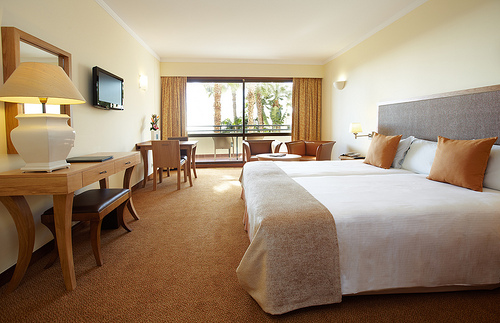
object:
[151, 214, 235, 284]
carpet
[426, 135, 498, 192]
pillow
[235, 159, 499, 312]
bed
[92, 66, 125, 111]
tv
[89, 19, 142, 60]
wall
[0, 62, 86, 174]
lamp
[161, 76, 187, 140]
curtains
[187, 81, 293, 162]
door